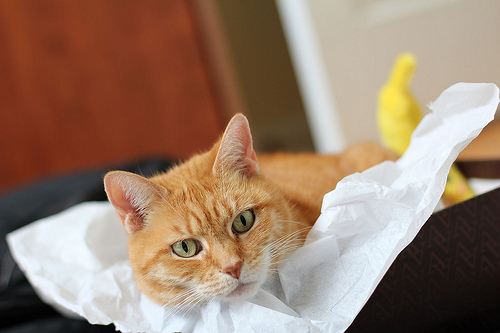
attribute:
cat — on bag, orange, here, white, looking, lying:
[104, 112, 403, 315]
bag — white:
[6, 81, 499, 332]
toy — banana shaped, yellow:
[375, 53, 470, 203]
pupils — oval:
[182, 212, 248, 254]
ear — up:
[211, 111, 255, 176]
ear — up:
[102, 168, 163, 230]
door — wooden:
[0, 1, 226, 192]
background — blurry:
[0, 0, 498, 193]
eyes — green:
[170, 206, 257, 259]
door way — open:
[0, 0, 321, 177]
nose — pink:
[222, 258, 244, 280]